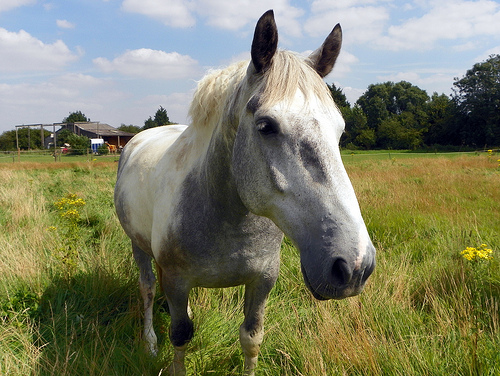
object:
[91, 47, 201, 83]
cloud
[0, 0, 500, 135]
sky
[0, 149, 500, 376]
grass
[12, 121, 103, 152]
structure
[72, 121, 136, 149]
house